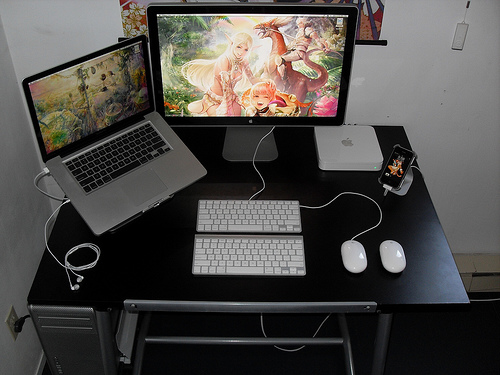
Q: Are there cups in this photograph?
A: No, there are no cups.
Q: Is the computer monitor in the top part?
A: Yes, the computer monitor is in the top of the image.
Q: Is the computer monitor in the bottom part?
A: No, the computer monitor is in the top of the image.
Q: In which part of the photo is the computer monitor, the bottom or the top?
A: The computer monitor is in the top of the image.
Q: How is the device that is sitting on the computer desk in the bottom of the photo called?
A: The device is a computer monitor.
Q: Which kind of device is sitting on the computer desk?
A: The device is a computer monitor.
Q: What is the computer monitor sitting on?
A: The computer monitor is sitting on the computer desk.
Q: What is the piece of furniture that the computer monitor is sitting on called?
A: The piece of furniture is a computer desk.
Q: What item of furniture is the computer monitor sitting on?
A: The computer monitor is sitting on the computer desk.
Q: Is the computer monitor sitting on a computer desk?
A: Yes, the computer monitor is sitting on a computer desk.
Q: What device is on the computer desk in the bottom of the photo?
A: The device is a computer monitor.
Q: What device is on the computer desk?
A: The device is a computer monitor.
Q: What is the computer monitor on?
A: The computer monitor is on the computer desk.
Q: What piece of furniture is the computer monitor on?
A: The computer monitor is on the computer desk.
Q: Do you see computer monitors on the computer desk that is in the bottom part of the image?
A: Yes, there is a computer monitor on the computer desk.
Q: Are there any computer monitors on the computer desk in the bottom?
A: Yes, there is a computer monitor on the computer desk.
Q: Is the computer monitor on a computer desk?
A: Yes, the computer monitor is on a computer desk.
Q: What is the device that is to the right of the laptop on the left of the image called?
A: The device is a computer monitor.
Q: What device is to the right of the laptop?
A: The device is a computer monitor.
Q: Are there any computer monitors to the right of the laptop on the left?
A: Yes, there is a computer monitor to the right of the laptop.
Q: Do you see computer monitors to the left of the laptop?
A: No, the computer monitor is to the right of the laptop.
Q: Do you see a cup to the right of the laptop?
A: No, there is a computer monitor to the right of the laptop.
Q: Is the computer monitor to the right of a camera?
A: No, the computer monitor is to the right of the laptop.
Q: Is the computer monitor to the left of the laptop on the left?
A: No, the computer monitor is to the right of the laptop.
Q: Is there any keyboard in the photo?
A: Yes, there is a keyboard.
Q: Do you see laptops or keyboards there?
A: Yes, there is a keyboard.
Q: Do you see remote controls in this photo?
A: No, there are no remote controls.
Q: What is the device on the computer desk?
A: The device is a keyboard.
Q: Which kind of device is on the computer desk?
A: The device is a keyboard.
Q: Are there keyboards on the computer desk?
A: Yes, there is a keyboard on the computer desk.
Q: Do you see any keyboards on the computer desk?
A: Yes, there is a keyboard on the computer desk.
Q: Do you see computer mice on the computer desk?
A: No, there is a keyboard on the computer desk.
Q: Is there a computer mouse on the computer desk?
A: No, there is a keyboard on the computer desk.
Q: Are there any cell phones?
A: Yes, there is a cell phone.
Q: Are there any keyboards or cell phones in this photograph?
A: Yes, there is a cell phone.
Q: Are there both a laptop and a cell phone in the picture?
A: Yes, there are both a cell phone and a laptop.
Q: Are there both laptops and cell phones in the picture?
A: Yes, there are both a cell phone and a laptop.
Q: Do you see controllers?
A: No, there are no controllers.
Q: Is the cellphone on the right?
A: Yes, the cellphone is on the right of the image.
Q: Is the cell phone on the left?
A: No, the cell phone is on the right of the image.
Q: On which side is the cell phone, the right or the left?
A: The cell phone is on the right of the image.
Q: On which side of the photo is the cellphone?
A: The cellphone is on the right of the image.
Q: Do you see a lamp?
A: No, there are no lamps.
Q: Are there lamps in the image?
A: No, there are no lamps.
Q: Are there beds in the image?
A: No, there are no beds.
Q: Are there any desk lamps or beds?
A: No, there are no beds or desk lamps.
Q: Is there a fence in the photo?
A: No, there are no fences.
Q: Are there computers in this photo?
A: Yes, there is a computer.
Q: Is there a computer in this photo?
A: Yes, there is a computer.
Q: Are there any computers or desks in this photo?
A: Yes, there is a computer.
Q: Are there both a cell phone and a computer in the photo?
A: Yes, there are both a computer and a cell phone.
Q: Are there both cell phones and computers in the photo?
A: Yes, there are both a computer and a cell phone.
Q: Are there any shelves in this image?
A: No, there are no shelves.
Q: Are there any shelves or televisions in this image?
A: No, there are no shelves or televisions.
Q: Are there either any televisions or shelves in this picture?
A: No, there are no shelves or televisions.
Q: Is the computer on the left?
A: Yes, the computer is on the left of the image.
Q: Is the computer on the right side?
A: No, the computer is on the left of the image.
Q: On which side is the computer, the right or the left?
A: The computer is on the left of the image.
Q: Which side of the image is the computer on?
A: The computer is on the left of the image.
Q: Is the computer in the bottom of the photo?
A: Yes, the computer is in the bottom of the image.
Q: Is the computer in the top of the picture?
A: No, the computer is in the bottom of the image.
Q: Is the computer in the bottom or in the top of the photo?
A: The computer is in the bottom of the image.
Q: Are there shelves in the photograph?
A: No, there are no shelves.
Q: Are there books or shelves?
A: No, there are no shelves or books.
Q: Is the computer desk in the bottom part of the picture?
A: Yes, the computer desk is in the bottom of the image.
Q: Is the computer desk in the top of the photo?
A: No, the computer desk is in the bottom of the image.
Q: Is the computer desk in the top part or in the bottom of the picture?
A: The computer desk is in the bottom of the image.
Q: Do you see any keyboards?
A: Yes, there is a keyboard.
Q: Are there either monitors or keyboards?
A: Yes, there is a keyboard.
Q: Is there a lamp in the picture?
A: No, there are no lamps.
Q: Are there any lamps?
A: No, there are no lamps.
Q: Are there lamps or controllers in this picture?
A: No, there are no lamps or controllers.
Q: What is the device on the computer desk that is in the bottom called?
A: The device is a keyboard.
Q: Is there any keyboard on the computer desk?
A: Yes, there is a keyboard on the computer desk.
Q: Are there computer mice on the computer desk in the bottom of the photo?
A: No, there is a keyboard on the computer desk.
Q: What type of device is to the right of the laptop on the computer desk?
A: The device is a keyboard.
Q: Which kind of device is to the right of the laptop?
A: The device is a keyboard.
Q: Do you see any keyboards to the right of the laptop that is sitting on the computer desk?
A: Yes, there is a keyboard to the right of the laptop computer.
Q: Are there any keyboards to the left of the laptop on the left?
A: No, the keyboard is to the right of the laptop.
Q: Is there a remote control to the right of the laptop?
A: No, there is a keyboard to the right of the laptop.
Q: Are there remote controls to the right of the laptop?
A: No, there is a keyboard to the right of the laptop.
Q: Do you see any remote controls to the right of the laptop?
A: No, there is a keyboard to the right of the laptop.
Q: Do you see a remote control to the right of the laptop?
A: No, there is a keyboard to the right of the laptop.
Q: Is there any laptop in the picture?
A: Yes, there is a laptop.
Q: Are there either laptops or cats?
A: Yes, there is a laptop.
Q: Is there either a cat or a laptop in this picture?
A: Yes, there is a laptop.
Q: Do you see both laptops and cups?
A: No, there is a laptop but no cups.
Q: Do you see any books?
A: No, there are no books.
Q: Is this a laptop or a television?
A: This is a laptop.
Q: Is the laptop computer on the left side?
A: Yes, the laptop computer is on the left of the image.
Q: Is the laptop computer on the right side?
A: No, the laptop computer is on the left of the image.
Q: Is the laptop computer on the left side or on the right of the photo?
A: The laptop computer is on the left of the image.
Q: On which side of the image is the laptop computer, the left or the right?
A: The laptop computer is on the left of the image.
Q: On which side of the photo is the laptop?
A: The laptop is on the left of the image.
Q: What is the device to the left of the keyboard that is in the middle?
A: The device is a laptop.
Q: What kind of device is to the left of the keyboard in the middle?
A: The device is a laptop.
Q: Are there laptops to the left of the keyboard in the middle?
A: Yes, there is a laptop to the left of the keyboard.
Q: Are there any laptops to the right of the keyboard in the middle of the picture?
A: No, the laptop is to the left of the keyboard.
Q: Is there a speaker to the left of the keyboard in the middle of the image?
A: No, there is a laptop to the left of the keyboard.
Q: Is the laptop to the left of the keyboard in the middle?
A: Yes, the laptop is to the left of the keyboard.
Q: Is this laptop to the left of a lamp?
A: No, the laptop is to the left of the keyboard.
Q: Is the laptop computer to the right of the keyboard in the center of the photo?
A: No, the laptop computer is to the left of the keyboard.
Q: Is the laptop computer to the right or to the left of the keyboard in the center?
A: The laptop computer is to the left of the keyboard.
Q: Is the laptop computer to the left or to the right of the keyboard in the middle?
A: The laptop computer is to the left of the keyboard.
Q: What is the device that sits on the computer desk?
A: The device is a laptop.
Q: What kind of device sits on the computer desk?
A: The device is a laptop.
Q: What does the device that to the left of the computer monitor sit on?
A: The laptop sits on the computer desk.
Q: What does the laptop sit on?
A: The laptop sits on the computer desk.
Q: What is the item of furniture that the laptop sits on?
A: The piece of furniture is a computer desk.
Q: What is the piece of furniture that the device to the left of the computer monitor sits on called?
A: The piece of furniture is a computer desk.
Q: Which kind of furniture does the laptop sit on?
A: The laptop sits on the computer desk.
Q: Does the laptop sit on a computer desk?
A: Yes, the laptop sits on a computer desk.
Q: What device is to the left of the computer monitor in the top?
A: The device is a laptop.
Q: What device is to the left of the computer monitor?
A: The device is a laptop.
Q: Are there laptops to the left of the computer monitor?
A: Yes, there is a laptop to the left of the computer monitor.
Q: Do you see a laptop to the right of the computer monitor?
A: No, the laptop is to the left of the computer monitor.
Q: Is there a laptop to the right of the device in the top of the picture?
A: No, the laptop is to the left of the computer monitor.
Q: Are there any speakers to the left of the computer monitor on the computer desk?
A: No, there is a laptop to the left of the computer monitor.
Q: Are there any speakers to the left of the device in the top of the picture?
A: No, there is a laptop to the left of the computer monitor.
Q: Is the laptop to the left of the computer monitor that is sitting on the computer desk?
A: Yes, the laptop is to the left of the computer monitor.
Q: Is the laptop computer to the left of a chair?
A: No, the laptop computer is to the left of the computer monitor.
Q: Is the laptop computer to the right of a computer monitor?
A: No, the laptop computer is to the left of a computer monitor.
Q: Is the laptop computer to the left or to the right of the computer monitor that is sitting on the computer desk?
A: The laptop computer is to the left of the computer monitor.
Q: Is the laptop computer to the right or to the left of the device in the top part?
A: The laptop computer is to the left of the computer monitor.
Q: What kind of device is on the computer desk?
A: The device is a laptop.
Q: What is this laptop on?
A: The laptop is on the computer desk.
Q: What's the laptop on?
A: The laptop is on the computer desk.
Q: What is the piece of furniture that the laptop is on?
A: The piece of furniture is a computer desk.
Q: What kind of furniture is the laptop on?
A: The laptop is on the computer desk.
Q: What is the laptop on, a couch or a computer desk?
A: The laptop is on a computer desk.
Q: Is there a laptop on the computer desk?
A: Yes, there is a laptop on the computer desk.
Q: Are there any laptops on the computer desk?
A: Yes, there is a laptop on the computer desk.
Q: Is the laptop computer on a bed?
A: No, the laptop computer is on the computer desk.